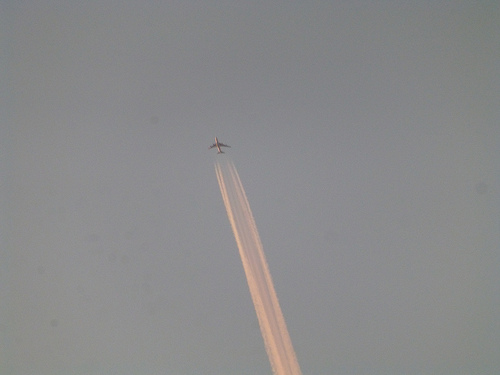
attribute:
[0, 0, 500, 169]
gray sky — dark grey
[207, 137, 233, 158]
plane — upward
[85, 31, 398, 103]
sky — dark